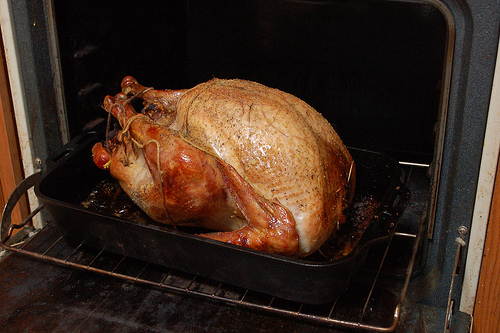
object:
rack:
[3, 160, 445, 332]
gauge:
[329, 275, 413, 330]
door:
[1, 49, 28, 239]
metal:
[10, 157, 434, 332]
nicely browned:
[86, 71, 320, 225]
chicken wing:
[194, 159, 298, 253]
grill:
[0, 212, 425, 332]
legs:
[100, 92, 225, 224]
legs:
[117, 75, 190, 120]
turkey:
[92, 74, 360, 259]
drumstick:
[90, 77, 226, 228]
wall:
[201, 6, 452, 123]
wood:
[464, 149, 500, 332]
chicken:
[92, 75, 358, 260]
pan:
[33, 121, 406, 302]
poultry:
[88, 72, 360, 253]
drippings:
[352, 192, 369, 250]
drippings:
[83, 172, 125, 212]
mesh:
[7, 159, 446, 327]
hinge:
[1, 166, 43, 241]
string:
[139, 107, 175, 138]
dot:
[286, 192, 296, 201]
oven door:
[3, 1, 490, 331]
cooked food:
[91, 75, 356, 256]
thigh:
[131, 162, 217, 226]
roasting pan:
[35, 127, 396, 307]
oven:
[43, 30, 462, 313]